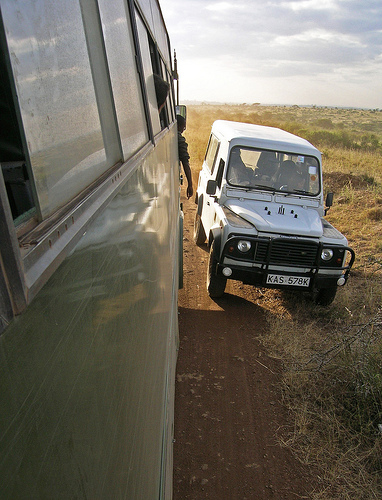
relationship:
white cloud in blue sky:
[153, 0, 382, 99] [162, 0, 378, 106]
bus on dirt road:
[0, 0, 187, 497] [179, 140, 331, 497]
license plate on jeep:
[262, 266, 313, 296] [187, 100, 360, 311]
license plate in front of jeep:
[266, 274, 310, 288] [193, 117, 356, 307]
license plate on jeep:
[266, 274, 310, 288] [193, 117, 356, 307]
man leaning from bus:
[278, 159, 307, 194] [3, 4, 197, 496]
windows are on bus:
[0, 0, 154, 236] [3, 4, 197, 496]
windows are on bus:
[223, 136, 328, 203] [3, 4, 197, 496]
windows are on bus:
[197, 125, 223, 174] [3, 4, 197, 496]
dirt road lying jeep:
[178, 142, 306, 499] [193, 117, 356, 307]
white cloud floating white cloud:
[153, 0, 382, 99] [153, 0, 382, 99]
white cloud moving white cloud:
[203, 0, 256, 18] [153, 0, 382, 99]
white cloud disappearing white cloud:
[153, 0, 382, 99] [153, 0, 382, 99]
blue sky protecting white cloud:
[162, 0, 378, 106] [153, 0, 382, 99]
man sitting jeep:
[285, 177, 327, 194] [193, 117, 356, 307]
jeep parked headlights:
[163, 110, 361, 305] [199, 209, 353, 295]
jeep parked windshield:
[193, 117, 356, 307] [225, 143, 322, 197]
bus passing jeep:
[3, 4, 197, 496] [193, 117, 356, 307]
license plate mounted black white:
[266, 274, 310, 288] [267, 273, 311, 288]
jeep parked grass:
[193, 117, 356, 307] [266, 320, 380, 498]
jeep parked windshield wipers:
[193, 117, 356, 307] [293, 186, 315, 194]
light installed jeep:
[234, 237, 251, 253] [193, 117, 356, 307]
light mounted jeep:
[319, 246, 334, 260] [193, 117, 356, 307]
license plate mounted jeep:
[266, 274, 310, 288] [193, 117, 356, 307]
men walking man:
[139, 61, 173, 134] [172, 104, 194, 200]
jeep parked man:
[193, 117, 356, 307] [172, 104, 194, 200]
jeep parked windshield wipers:
[193, 117, 356, 307] [253, 181, 280, 193]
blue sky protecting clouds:
[162, 0, 378, 106] [223, 33, 341, 81]